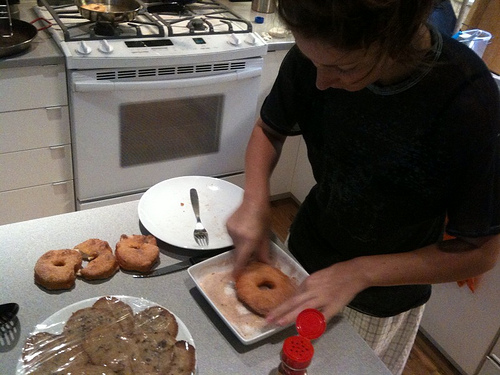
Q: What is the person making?
A: Donuts.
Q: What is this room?
A: Kitchen.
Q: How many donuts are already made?
A: Three.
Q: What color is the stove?
A: White.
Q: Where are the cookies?
A: On a plate.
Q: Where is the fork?
A: On a plate.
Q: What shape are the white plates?
A: Round.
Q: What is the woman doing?
A: Putting sugar on a pastry.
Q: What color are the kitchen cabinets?
A: White.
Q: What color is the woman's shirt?
A: Black.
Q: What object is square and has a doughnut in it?
A: A plate.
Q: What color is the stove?
A: White.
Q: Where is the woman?
A: Kitchen.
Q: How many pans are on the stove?
A: One.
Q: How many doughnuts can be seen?
A: Four.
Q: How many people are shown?
A: 1.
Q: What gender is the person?
A: Female.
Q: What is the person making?
A: Doughnuts.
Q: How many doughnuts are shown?
A: 4.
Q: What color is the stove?
A: White.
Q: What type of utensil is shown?
A: Fork.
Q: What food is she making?
A: Doughnuts.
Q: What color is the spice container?
A: Red.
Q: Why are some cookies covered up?
A: So they don't get stale.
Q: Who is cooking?
A: The woman.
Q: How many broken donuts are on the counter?
A: Three.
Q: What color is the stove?
A: White.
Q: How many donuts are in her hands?
A: One.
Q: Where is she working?
A: In a kitchen.